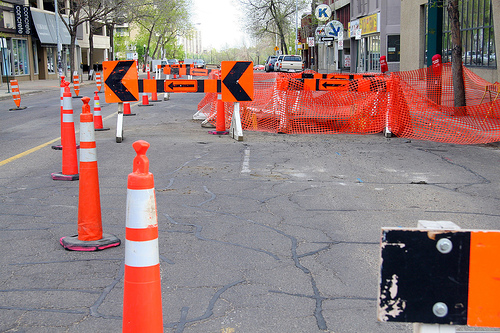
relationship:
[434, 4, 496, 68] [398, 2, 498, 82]
windows on building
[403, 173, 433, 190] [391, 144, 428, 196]
hole in ground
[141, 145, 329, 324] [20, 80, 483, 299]
cracks in road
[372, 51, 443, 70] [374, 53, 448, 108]
bags over meters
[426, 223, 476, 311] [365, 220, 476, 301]
bolts on barrier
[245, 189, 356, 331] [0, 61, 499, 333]
lines in city street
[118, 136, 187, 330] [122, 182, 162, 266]
cone has stripes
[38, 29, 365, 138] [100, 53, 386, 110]
arrows on signs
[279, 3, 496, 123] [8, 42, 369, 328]
businesses on side of street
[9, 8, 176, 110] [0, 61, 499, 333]
businesses on side of city street